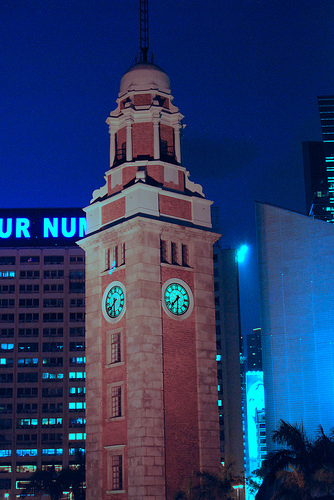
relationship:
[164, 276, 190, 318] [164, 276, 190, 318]
clock tower illuminated clock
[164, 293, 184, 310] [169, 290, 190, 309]
hand on clock on clock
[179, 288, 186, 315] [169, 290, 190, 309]
numbers on clock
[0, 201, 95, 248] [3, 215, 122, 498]
lights on top on building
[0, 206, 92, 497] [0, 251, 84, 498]
building has windows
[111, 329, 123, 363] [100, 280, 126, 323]
window under clock face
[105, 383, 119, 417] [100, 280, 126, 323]
window under clock face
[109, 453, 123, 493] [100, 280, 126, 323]
window under clock face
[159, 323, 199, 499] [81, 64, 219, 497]
red bricks on building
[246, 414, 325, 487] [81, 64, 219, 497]
palm trees in front of building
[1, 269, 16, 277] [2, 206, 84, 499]
light in building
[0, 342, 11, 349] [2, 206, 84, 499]
light in building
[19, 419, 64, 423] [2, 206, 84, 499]
light in building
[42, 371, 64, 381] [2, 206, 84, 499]
light in building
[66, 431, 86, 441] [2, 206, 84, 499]
light in building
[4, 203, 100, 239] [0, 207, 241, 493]
words on building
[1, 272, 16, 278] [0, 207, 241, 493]
windows in building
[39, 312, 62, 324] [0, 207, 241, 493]
windows in building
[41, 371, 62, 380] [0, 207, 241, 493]
windows in building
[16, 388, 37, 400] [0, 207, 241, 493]
windows in building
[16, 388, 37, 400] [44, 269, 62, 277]
windows in windows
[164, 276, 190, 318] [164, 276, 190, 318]
clock has clock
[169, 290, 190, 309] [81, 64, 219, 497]
clock on building